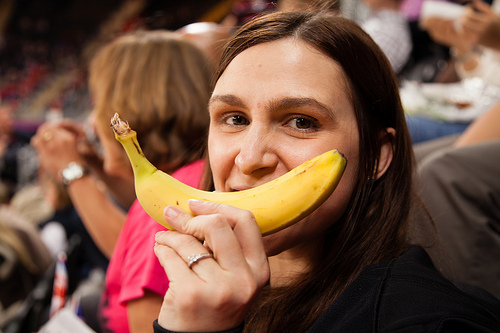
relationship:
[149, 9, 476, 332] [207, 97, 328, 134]
woman with eyes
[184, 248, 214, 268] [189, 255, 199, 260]
ring has diamond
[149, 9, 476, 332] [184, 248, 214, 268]
woman wearing ring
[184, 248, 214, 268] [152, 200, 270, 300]
ring on finger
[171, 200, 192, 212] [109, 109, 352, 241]
spot on banana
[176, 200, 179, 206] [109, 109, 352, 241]
spot on banana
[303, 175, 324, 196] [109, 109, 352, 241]
spot on banana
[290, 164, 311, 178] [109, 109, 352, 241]
spot on banana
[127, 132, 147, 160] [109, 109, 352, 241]
spot on banana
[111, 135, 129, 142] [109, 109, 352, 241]
spot on banana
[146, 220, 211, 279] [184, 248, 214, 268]
finger with ring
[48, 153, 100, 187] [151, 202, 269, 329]
watch on arm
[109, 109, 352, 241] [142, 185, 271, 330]
banana held with hand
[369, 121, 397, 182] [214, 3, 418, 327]
ear poking through hair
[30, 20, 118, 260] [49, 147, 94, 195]
person wearing watch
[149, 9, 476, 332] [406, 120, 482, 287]
woman wearing pants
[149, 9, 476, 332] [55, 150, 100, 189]
woman wearing watch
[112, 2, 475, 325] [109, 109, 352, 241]
woman holding banana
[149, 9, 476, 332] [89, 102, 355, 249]
woman eating banana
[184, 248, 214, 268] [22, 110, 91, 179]
ring on hand